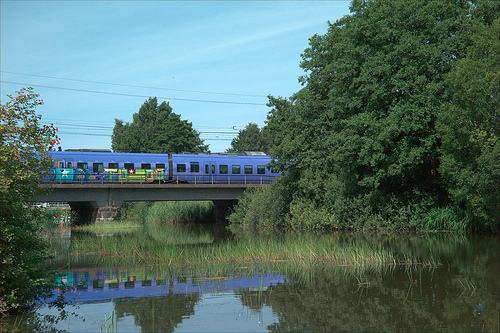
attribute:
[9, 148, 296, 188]
train — long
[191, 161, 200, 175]
window — square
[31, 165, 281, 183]
guard rail — black, small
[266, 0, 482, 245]
tree — green, poking, thick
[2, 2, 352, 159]
sky — blue, clear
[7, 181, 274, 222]
bridge — designed, cement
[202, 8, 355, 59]
cloud — white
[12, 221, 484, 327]
water — tiny